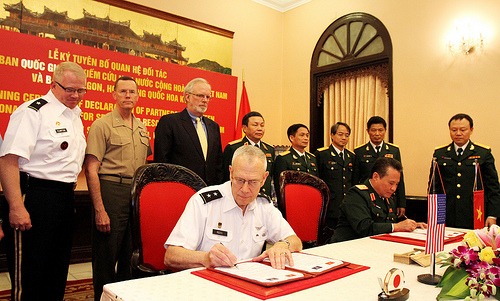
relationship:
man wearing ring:
[164, 146, 296, 273] [275, 248, 292, 258]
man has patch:
[164, 146, 296, 273] [215, 219, 227, 231]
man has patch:
[164, 146, 296, 273] [198, 192, 227, 204]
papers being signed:
[201, 247, 344, 289] [212, 257, 253, 268]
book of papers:
[213, 228, 344, 297] [201, 247, 344, 289]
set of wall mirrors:
[297, 11, 398, 118] [306, 12, 401, 119]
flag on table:
[427, 195, 447, 252] [86, 218, 499, 283]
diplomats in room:
[1, 56, 499, 238] [4, 1, 497, 296]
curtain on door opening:
[311, 79, 393, 165] [306, 18, 396, 215]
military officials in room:
[1, 56, 499, 238] [4, 1, 497, 296]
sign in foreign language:
[4, 28, 254, 158] [27, 39, 184, 95]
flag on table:
[420, 191, 455, 252] [86, 218, 499, 283]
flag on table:
[465, 184, 490, 234] [86, 218, 499, 283]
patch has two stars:
[198, 192, 227, 204] [200, 186, 224, 200]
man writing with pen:
[164, 146, 296, 273] [217, 248, 244, 270]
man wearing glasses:
[164, 146, 296, 273] [227, 165, 270, 185]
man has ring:
[164, 146, 296, 273] [275, 248, 292, 258]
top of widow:
[306, 19, 406, 74] [301, 14, 398, 74]